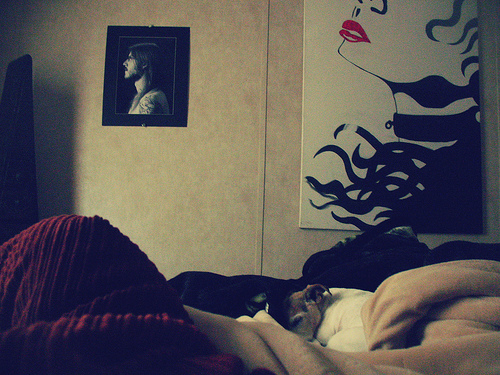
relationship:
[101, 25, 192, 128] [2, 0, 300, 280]
frame hanging on wall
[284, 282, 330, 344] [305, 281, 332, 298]
dog has ear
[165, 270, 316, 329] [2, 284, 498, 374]
dog laying on bed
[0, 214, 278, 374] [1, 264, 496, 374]
blanket on bed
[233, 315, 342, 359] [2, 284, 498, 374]
blanket on bed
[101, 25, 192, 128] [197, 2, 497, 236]
frame hanging on wall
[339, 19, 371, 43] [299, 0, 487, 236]
lips on painting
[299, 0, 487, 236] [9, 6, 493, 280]
painting on wall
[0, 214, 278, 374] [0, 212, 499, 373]
blanket on bed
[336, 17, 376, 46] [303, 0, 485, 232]
lips of woman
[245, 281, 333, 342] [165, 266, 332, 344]
head of dog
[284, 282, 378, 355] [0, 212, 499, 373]
dog in bed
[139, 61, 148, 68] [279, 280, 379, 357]
ear of dog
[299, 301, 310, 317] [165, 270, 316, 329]
eye of dog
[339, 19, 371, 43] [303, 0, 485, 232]
lips of woman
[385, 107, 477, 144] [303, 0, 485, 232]
choker of woman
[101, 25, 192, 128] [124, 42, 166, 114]
frame of man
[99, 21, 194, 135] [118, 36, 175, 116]
frame around picture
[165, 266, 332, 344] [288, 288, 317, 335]
dog has eyes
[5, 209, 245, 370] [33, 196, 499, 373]
blanket on bed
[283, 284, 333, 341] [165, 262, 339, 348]
head on sleeping dog